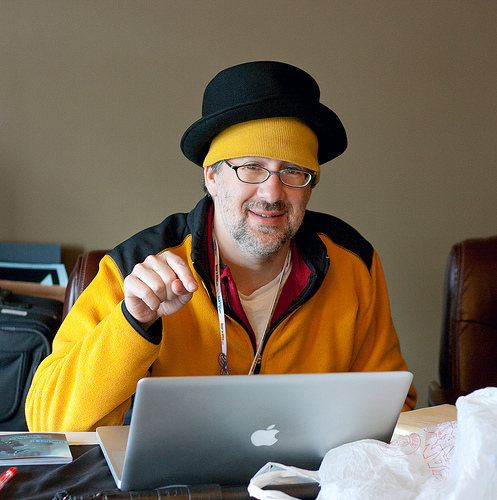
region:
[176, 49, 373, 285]
Black and yellow hats on man's head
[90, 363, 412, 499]
Silver apple laptop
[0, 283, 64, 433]
Black bag with handle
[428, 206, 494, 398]
Brown leather chair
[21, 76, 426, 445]
Man wearing a yellow and black sweater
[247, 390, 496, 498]
White plastic grocery bag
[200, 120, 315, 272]
Man with mostly grey beard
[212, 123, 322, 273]
Man wearing eyeglasses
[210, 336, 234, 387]
Blue ribbon pin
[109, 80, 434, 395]
Man wearing white under shirt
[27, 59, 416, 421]
a man wearing two hats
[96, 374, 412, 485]
an Apple Macbook Pro laptop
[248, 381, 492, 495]
a plastic shopping bag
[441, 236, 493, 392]
a dark brown office chair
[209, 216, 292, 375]
a lanyard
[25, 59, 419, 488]
a man pointing at a laptop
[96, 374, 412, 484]
a laptop computer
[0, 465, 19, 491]
the end of a red pen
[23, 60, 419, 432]
a man with glasses wearing a zip up fleece sweater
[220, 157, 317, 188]
a pair of glasses being worn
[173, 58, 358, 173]
Black felt hat on top of a yellow knit hat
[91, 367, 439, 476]
An open Apple laptop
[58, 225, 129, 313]
A brown leather chair being used by a man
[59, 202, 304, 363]
A man wearing a yellow jacket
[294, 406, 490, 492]
A white plastic bag sits on the table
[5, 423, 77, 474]
A book rests next to the laptop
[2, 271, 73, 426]
A black computer bag beside the man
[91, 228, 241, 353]
Pointing at the screen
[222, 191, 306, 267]
A salt and pepper beard and moustache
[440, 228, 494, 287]
An empty brown leather chair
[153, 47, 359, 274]
man wearing black hat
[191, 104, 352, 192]
man wearing yellow knit cap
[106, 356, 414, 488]
silver apple laptop on table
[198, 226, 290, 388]
key lanyard around neck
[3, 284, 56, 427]
black suitcase in background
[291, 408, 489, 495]
empty plastic shopping bag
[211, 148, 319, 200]
man wearing eyeglasses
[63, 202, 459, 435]
man wearing yellow and black jacket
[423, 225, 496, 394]
brown leather desk chair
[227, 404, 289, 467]
apple icon on laptop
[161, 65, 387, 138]
A black top hat.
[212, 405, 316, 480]
The apple computer symbol.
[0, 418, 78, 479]
Book on a table.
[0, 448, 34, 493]
Red pen on table.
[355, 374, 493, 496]
White grocery bag with red writing.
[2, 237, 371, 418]
Yellow and black jacket.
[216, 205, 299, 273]
Goatee on a man.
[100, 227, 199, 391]
A hand pointing a finger.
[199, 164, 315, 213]
A pair of glasses.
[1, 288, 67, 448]
A tall black suit case.